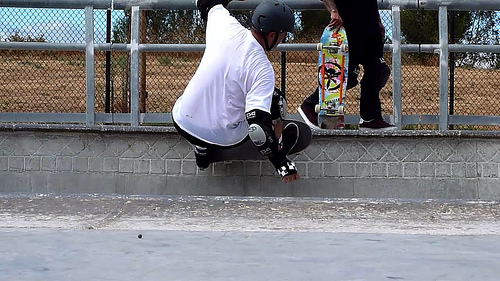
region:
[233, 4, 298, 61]
a man wearing a black hat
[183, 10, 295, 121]
a man wearing a white shirt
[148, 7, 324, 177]
a man doing a trick on a skateboard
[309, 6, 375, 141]
someone holding a skateboard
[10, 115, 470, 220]
a small concrete wall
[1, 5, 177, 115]
a metal railing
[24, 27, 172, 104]
a chain link fence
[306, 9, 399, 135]
a person wearing black pants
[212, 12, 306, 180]
a man wearing a elbow pad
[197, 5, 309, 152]
a man with facial hair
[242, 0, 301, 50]
matte black safety helmet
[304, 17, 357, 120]
multi colored skate board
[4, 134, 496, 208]
low gray cement wall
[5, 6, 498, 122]
silver metal chain link fence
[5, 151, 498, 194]
row of decorative squares in wall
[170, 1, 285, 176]
men's white tee shirt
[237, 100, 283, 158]
black and gray elbow pad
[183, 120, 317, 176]
skateboard on top of low wall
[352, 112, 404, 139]
black and white skate shoes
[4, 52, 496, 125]
brown and gold grass field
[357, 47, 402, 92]
knee pads are black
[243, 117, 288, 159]
elbow pads are silver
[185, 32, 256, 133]
the shirt is white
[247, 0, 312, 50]
the helmet is black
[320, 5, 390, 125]
guy is holding skateboard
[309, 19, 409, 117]
the skateboard is colorful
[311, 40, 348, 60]
the wheels on the skateboard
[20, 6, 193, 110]
the fence is black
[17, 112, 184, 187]
the sidewalk is gray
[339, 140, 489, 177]
design is on sidewalk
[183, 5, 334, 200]
skateboarder on side of wall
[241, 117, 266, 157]
elbow pad on skateboarder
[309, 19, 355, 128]
skateboard in person's hand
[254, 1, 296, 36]
black helmet on man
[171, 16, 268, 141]
white tshirt on man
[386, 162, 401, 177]
square brick on wall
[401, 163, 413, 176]
square brick on wall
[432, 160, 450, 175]
square brick on wall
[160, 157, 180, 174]
square brick on wall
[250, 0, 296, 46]
a black skateboard safety helmet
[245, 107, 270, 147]
black safety elbow pads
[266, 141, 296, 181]
black and white wrist pad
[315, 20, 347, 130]
custom art design on a skateboard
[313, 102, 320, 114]
white polyurethane skateboard wheels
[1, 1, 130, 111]
a black chain link fence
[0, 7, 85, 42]
blue sky with some white clouds in the distance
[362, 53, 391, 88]
safety knee pad guards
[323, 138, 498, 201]
a small concrete wall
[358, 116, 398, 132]
black and white skateboard shoes